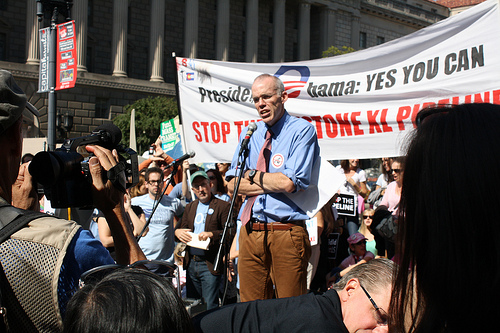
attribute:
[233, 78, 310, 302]
man — speaking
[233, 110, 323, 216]
shirt — blue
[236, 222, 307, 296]
pants — brown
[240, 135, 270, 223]
tie — red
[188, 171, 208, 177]
cap — green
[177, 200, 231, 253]
jacket — brown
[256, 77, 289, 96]
hair — grey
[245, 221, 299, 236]
belt — brown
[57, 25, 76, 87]
pennant — red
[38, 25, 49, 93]
pennant — grey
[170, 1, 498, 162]
sign — white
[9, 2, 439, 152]
building — in back, large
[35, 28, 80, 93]
banners — small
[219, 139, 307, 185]
sleeves — rolled-up